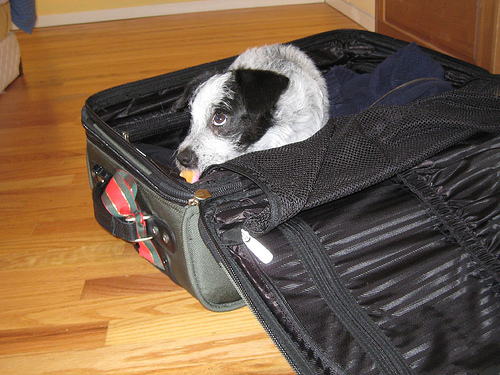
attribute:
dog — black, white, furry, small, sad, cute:
[166, 37, 330, 196]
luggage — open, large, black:
[82, 26, 499, 374]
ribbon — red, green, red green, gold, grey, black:
[98, 165, 170, 269]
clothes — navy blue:
[325, 43, 452, 112]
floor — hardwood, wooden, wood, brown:
[2, 2, 368, 373]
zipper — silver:
[119, 128, 133, 142]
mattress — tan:
[2, 0, 26, 101]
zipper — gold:
[183, 189, 215, 211]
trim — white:
[12, 1, 375, 32]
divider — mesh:
[190, 76, 499, 237]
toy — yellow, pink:
[174, 165, 201, 185]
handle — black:
[89, 164, 178, 254]